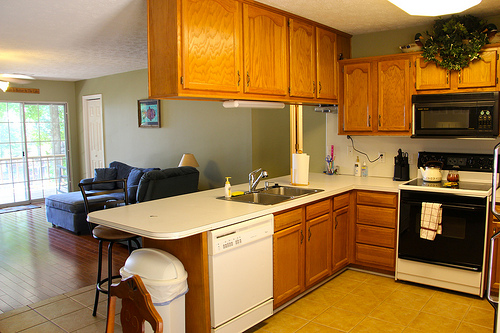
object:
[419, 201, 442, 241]
dish towel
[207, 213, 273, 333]
dishwasher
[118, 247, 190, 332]
trashcan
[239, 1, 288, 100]
cabinets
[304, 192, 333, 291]
cabinets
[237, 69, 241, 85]
handles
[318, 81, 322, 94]
handles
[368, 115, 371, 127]
handles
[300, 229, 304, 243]
handles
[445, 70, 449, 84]
handles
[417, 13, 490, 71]
plant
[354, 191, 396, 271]
drawers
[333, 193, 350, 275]
drawers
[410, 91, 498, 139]
microwave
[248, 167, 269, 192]
faucet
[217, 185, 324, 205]
sink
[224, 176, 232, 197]
soap bottle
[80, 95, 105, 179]
door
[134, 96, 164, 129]
picture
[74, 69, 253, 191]
wall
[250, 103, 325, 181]
wall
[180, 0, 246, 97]
cabinet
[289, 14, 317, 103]
cabinet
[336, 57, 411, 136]
cabinet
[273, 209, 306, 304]
cabinet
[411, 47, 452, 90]
cabinet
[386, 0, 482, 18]
light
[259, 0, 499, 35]
ceiling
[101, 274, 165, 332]
chair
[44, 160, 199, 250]
couch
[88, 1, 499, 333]
kitchen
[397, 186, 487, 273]
oven door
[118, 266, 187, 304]
bag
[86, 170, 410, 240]
counter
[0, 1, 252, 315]
livig room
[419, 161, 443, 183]
tea kettle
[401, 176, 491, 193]
stove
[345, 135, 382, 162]
cord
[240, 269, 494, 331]
floor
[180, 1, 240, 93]
cabinet door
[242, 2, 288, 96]
cabinet door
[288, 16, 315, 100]
cabinet door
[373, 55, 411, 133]
cabinet door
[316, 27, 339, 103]
cabinet door